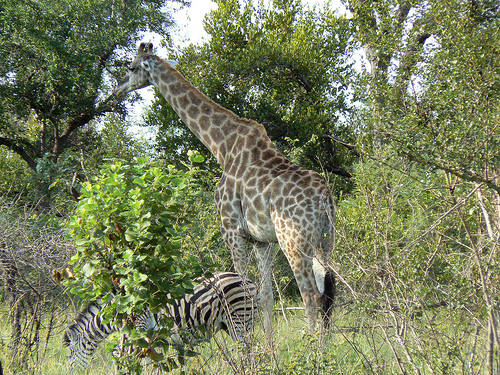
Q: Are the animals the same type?
A: No, they are giraffes and zebras.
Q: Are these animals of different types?
A: Yes, they are giraffes and zebras.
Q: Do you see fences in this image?
A: No, there are no fences.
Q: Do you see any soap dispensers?
A: No, there are no soap dispensers.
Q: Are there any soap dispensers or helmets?
A: No, there are no soap dispensers or helmets.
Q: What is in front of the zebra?
A: The shrub is in front of the zebra.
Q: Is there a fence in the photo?
A: No, there are no fences.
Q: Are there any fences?
A: No, there are no fences.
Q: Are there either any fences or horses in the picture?
A: No, there are no fences or horses.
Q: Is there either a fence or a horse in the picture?
A: No, there are no fences or horses.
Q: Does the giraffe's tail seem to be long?
A: Yes, the tail is long.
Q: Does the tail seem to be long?
A: Yes, the tail is long.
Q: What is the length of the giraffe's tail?
A: The tail is long.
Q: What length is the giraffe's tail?
A: The tail is long.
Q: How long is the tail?
A: The tail is long.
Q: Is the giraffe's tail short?
A: No, the tail is long.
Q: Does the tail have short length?
A: No, the tail is long.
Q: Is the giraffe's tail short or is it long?
A: The tail is long.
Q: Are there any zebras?
A: Yes, there is a zebra.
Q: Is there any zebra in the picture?
A: Yes, there is a zebra.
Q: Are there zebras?
A: Yes, there is a zebra.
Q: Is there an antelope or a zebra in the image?
A: Yes, there is a zebra.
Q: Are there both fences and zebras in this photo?
A: No, there is a zebra but no fences.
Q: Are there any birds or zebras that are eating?
A: Yes, the zebra is eating.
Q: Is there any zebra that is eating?
A: Yes, there is a zebra that is eating.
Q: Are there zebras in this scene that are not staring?
A: Yes, there is a zebra that is eating.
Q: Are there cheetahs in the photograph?
A: No, there are no cheetahs.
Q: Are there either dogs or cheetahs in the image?
A: No, there are no cheetahs or dogs.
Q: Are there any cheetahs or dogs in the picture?
A: No, there are no cheetahs or dogs.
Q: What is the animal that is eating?
A: The animal is a zebra.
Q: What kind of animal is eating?
A: The animal is a zebra.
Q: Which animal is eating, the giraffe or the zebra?
A: The zebra is eating.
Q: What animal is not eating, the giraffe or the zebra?
A: The giraffe is not eating.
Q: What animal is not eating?
A: The animal is a giraffe.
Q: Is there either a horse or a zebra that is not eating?
A: No, there is a zebra but it is eating.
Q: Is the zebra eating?
A: Yes, the zebra is eating.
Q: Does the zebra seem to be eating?
A: Yes, the zebra is eating.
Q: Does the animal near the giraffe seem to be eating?
A: Yes, the zebra is eating.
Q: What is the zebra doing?
A: The zebra is eating.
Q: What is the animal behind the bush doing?
A: The zebra is eating.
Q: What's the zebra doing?
A: The zebra is eating.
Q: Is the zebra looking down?
A: No, the zebra is eating.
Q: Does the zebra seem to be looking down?
A: No, the zebra is eating.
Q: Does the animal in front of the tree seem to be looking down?
A: No, the zebra is eating.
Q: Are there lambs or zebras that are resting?
A: No, there is a zebra but it is eating.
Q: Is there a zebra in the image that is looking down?
A: No, there is a zebra but it is eating.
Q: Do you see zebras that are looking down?
A: No, there is a zebra but it is eating.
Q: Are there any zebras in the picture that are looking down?
A: No, there is a zebra but it is eating.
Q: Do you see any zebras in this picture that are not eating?
A: No, there is a zebra but it is eating.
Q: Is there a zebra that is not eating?
A: No, there is a zebra but it is eating.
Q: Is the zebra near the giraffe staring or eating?
A: The zebra is eating.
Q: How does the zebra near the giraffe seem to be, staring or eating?
A: The zebra is eating.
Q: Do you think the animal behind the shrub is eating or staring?
A: The zebra is eating.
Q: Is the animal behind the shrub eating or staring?
A: The zebra is eating.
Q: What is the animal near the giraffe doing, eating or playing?
A: The zebra is eating.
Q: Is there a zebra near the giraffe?
A: Yes, there is a zebra near the giraffe.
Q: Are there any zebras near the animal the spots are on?
A: Yes, there is a zebra near the giraffe.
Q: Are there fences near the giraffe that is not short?
A: No, there is a zebra near the giraffe.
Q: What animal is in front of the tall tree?
A: The zebra is in front of the tree.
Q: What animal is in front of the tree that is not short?
A: The animal is a zebra.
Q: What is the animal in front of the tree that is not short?
A: The animal is a zebra.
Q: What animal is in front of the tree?
A: The animal is a zebra.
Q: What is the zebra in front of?
A: The zebra is in front of the tree.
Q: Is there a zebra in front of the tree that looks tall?
A: Yes, there is a zebra in front of the tree.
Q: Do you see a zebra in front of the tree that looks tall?
A: Yes, there is a zebra in front of the tree.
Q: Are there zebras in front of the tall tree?
A: Yes, there is a zebra in front of the tree.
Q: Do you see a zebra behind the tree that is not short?
A: No, the zebra is in front of the tree.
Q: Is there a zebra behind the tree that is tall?
A: No, the zebra is in front of the tree.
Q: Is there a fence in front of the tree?
A: No, there is a zebra in front of the tree.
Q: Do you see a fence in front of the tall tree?
A: No, there is a zebra in front of the tree.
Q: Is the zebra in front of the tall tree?
A: Yes, the zebra is in front of the tree.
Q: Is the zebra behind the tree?
A: No, the zebra is in front of the tree.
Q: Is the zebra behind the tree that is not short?
A: No, the zebra is in front of the tree.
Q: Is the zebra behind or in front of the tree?
A: The zebra is in front of the tree.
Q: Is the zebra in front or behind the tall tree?
A: The zebra is in front of the tree.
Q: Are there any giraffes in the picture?
A: Yes, there is a giraffe.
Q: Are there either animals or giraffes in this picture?
A: Yes, there is a giraffe.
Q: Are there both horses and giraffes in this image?
A: No, there is a giraffe but no horses.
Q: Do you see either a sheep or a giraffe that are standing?
A: Yes, the giraffe is standing.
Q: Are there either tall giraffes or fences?
A: Yes, there is a tall giraffe.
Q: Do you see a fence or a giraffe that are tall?
A: Yes, the giraffe is tall.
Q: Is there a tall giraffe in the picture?
A: Yes, there is a tall giraffe.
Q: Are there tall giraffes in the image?
A: Yes, there is a tall giraffe.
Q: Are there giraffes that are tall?
A: Yes, there is a giraffe that is tall.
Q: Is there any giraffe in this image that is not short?
A: Yes, there is a tall giraffe.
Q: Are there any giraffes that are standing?
A: Yes, there is a giraffe that is standing.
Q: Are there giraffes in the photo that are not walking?
A: Yes, there is a giraffe that is standing.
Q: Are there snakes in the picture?
A: No, there are no snakes.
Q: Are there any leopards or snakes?
A: No, there are no snakes or leopards.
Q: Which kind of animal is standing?
A: The animal is a giraffe.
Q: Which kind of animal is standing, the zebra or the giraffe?
A: The giraffe is standing.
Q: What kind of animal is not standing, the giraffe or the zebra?
A: The zebra is not standing.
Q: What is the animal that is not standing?
A: The animal is a zebra.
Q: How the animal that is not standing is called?
A: The animal is a zebra.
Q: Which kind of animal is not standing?
A: The animal is a zebra.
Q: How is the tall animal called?
A: The animal is a giraffe.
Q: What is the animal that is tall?
A: The animal is a giraffe.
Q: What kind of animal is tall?
A: The animal is a giraffe.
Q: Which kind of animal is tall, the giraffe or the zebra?
A: The giraffe is tall.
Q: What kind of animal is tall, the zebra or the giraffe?
A: The giraffe is tall.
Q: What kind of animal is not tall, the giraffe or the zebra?
A: The zebra is not tall.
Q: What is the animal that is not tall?
A: The animal is a zebra.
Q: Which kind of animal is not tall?
A: The animal is a zebra.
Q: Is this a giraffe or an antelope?
A: This is a giraffe.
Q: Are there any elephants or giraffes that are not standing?
A: No, there is a giraffe but it is standing.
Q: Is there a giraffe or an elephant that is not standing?
A: No, there is a giraffe but it is standing.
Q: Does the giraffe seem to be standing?
A: Yes, the giraffe is standing.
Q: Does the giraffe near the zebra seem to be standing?
A: Yes, the giraffe is standing.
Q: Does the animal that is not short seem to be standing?
A: Yes, the giraffe is standing.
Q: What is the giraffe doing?
A: The giraffe is standing.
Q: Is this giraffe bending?
A: No, the giraffe is standing.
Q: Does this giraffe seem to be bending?
A: No, the giraffe is standing.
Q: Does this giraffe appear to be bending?
A: No, the giraffe is standing.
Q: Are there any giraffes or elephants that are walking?
A: No, there is a giraffe but it is standing.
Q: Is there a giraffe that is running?
A: No, there is a giraffe but it is standing.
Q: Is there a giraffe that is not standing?
A: No, there is a giraffe but it is standing.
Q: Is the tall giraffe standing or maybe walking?
A: The giraffe is standing.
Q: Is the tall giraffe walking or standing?
A: The giraffe is standing.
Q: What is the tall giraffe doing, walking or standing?
A: The giraffe is standing.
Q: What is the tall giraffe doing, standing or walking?
A: The giraffe is standing.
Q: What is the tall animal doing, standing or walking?
A: The giraffe is standing.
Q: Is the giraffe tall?
A: Yes, the giraffe is tall.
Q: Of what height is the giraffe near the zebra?
A: The giraffe is tall.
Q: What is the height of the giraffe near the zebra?
A: The giraffe is tall.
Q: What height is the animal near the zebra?
A: The giraffe is tall.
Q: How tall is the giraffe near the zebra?
A: The giraffe is tall.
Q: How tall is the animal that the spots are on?
A: The giraffe is tall.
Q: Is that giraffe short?
A: No, the giraffe is tall.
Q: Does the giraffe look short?
A: No, the giraffe is tall.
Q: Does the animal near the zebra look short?
A: No, the giraffe is tall.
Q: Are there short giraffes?
A: No, there is a giraffe but it is tall.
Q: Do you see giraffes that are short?
A: No, there is a giraffe but it is tall.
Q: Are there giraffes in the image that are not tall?
A: No, there is a giraffe but it is tall.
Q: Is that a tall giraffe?
A: Yes, that is a tall giraffe.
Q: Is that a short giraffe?
A: No, that is a tall giraffe.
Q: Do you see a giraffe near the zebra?
A: Yes, there is a giraffe near the zebra.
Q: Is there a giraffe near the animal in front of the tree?
A: Yes, there is a giraffe near the zebra.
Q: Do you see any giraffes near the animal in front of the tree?
A: Yes, there is a giraffe near the zebra.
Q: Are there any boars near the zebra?
A: No, there is a giraffe near the zebra.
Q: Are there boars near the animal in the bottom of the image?
A: No, there is a giraffe near the zebra.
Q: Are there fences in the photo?
A: No, there are no fences.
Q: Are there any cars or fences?
A: No, there are no fences or cars.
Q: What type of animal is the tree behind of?
A: The tree is behind the zebra.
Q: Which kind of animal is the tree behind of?
A: The tree is behind the zebra.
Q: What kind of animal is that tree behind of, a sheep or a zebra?
A: The tree is behind a zebra.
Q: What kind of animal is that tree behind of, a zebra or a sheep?
A: The tree is behind a zebra.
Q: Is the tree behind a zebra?
A: Yes, the tree is behind a zebra.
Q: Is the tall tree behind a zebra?
A: Yes, the tree is behind a zebra.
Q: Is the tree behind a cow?
A: No, the tree is behind a zebra.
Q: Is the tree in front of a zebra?
A: No, the tree is behind a zebra.